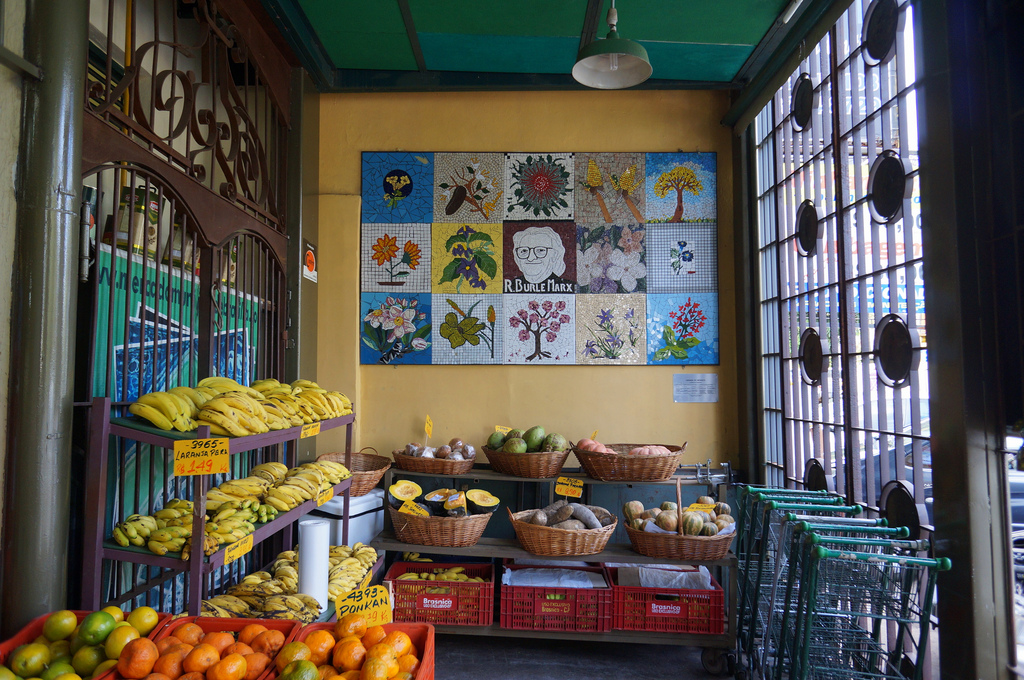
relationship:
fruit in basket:
[624, 493, 743, 537] [626, 474, 752, 565]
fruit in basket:
[518, 504, 614, 535] [486, 491, 631, 558]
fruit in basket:
[380, 476, 514, 520] [386, 471, 514, 560]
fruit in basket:
[485, 424, 579, 457] [481, 419, 575, 487]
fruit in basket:
[403, 424, 490, 459] [391, 409, 489, 470]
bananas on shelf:
[114, 365, 199, 446] [92, 409, 384, 459]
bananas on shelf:
[256, 459, 313, 514] [97, 407, 368, 451]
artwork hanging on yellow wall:
[323, 78, 749, 482] [302, 72, 776, 507]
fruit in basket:
[622, 496, 734, 537] [624, 476, 743, 559]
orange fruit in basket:
[280, 597, 417, 675] [257, 597, 433, 675]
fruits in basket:
[121, 621, 283, 679] [97, 605, 305, 675]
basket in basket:
[0, 609, 172, 680] [0, 597, 201, 669]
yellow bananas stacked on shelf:
[103, 359, 369, 435] [109, 412, 356, 455]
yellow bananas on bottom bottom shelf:
[170, 525, 423, 632] [194, 530, 411, 624]